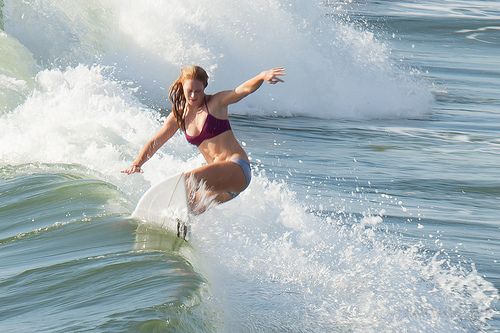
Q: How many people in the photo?
A: 1.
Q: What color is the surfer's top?
A: Maroon.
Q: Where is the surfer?
A: In the water.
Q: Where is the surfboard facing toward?
A: The camera.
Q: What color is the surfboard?
A: White.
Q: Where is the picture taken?
A: Ocean.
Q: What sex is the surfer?
A: Female.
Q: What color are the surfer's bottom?
A: Blue.